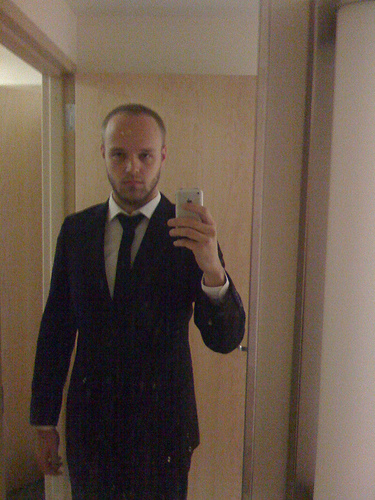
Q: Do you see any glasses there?
A: No, there are no glasses.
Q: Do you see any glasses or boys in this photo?
A: No, there are no glasses or boys.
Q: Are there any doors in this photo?
A: Yes, there is a door.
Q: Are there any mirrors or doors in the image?
A: Yes, there is a door.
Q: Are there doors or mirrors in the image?
A: Yes, there is a door.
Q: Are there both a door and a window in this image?
A: No, there is a door but no windows.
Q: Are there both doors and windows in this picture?
A: No, there is a door but no windows.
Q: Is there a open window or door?
A: Yes, there is an open door.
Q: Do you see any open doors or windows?
A: Yes, there is an open door.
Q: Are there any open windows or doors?
A: Yes, there is an open door.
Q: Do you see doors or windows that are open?
A: Yes, the door is open.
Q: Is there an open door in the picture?
A: Yes, there is an open door.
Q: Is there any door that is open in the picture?
A: Yes, there is an open door.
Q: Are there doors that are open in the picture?
A: Yes, there is an open door.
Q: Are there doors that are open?
A: Yes, there is a door that is open.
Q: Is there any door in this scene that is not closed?
A: Yes, there is a open door.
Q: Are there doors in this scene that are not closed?
A: Yes, there is a open door.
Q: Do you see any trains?
A: No, there are no trains.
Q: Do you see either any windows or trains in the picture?
A: No, there are no trains or windows.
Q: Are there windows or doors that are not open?
A: No, there is a door but it is open.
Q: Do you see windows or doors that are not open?
A: No, there is a door but it is open.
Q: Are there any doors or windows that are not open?
A: No, there is a door but it is open.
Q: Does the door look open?
A: Yes, the door is open.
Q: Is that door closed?
A: No, the door is open.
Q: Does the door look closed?
A: No, the door is open.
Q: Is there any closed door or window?
A: No, there is a door but it is open.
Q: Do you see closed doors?
A: No, there is a door but it is open.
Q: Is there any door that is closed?
A: No, there is a door but it is open.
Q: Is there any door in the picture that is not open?
A: No, there is a door but it is open.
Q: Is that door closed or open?
A: The door is open.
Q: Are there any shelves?
A: No, there are no shelves.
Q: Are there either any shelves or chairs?
A: No, there are no shelves or chairs.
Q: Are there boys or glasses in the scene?
A: No, there are no boys or glasses.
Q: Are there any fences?
A: No, there are no fences.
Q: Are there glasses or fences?
A: No, there are no fences or glasses.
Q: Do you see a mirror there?
A: Yes, there is a mirror.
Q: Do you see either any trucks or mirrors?
A: Yes, there is a mirror.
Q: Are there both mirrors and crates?
A: No, there is a mirror but no crates.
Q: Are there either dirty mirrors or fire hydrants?
A: Yes, there is a dirty mirror.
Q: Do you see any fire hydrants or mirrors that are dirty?
A: Yes, the mirror is dirty.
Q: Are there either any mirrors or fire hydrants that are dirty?
A: Yes, the mirror is dirty.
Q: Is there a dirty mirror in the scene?
A: Yes, there is a dirty mirror.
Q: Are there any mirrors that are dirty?
A: Yes, there is a mirror that is dirty.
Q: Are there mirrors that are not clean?
A: Yes, there is a dirty mirror.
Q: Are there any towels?
A: No, there are no towels.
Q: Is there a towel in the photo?
A: No, there are no towels.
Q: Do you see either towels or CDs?
A: No, there are no towels or cds.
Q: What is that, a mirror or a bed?
A: That is a mirror.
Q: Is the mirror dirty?
A: Yes, the mirror is dirty.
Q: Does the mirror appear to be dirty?
A: Yes, the mirror is dirty.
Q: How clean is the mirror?
A: The mirror is dirty.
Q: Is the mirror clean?
A: No, the mirror is dirty.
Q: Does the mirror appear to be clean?
A: No, the mirror is dirty.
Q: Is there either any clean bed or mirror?
A: No, there is a mirror but it is dirty.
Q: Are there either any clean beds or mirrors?
A: No, there is a mirror but it is dirty.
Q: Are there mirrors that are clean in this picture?
A: No, there is a mirror but it is dirty.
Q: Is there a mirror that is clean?
A: No, there is a mirror but it is dirty.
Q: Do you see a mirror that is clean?
A: No, there is a mirror but it is dirty.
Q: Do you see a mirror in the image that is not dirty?
A: No, there is a mirror but it is dirty.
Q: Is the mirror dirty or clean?
A: The mirror is dirty.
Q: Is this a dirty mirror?
A: Yes, this is a dirty mirror.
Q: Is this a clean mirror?
A: No, this is a dirty mirror.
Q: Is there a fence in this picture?
A: No, there are no fences.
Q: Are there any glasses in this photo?
A: No, there are no glasses.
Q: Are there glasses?
A: No, there are no glasses.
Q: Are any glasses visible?
A: No, there are no glasses.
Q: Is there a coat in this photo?
A: Yes, there is a coat.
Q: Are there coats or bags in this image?
A: Yes, there is a coat.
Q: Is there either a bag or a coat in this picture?
A: Yes, there is a coat.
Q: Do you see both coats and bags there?
A: No, there is a coat but no bags.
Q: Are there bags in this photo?
A: No, there are no bags.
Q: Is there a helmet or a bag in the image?
A: No, there are no bags or helmets.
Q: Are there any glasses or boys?
A: No, there are no glasses or boys.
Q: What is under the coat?
A: The shirt is under the coat.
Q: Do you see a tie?
A: Yes, there is a tie.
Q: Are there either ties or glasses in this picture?
A: Yes, there is a tie.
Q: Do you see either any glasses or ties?
A: Yes, there is a tie.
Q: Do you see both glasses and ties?
A: No, there is a tie but no glasses.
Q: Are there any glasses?
A: No, there are no glasses.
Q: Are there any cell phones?
A: Yes, there is a cell phone.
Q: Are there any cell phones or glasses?
A: Yes, there is a cell phone.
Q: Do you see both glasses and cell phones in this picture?
A: No, there is a cell phone but no glasses.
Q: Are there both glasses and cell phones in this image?
A: No, there is a cell phone but no glasses.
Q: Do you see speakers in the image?
A: No, there are no speakers.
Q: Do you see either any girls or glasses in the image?
A: No, there are no glasses or girls.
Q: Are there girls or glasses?
A: No, there are no glasses or girls.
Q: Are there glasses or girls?
A: No, there are no glasses or girls.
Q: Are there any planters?
A: No, there are no planters.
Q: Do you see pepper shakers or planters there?
A: No, there are no planters or pepper shakers.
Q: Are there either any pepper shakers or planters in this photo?
A: No, there are no planters or pepper shakers.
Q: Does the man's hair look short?
A: Yes, the hair is short.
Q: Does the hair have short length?
A: Yes, the hair is short.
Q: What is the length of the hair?
A: The hair is short.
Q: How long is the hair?
A: The hair is short.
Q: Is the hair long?
A: No, the hair is short.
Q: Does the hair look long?
A: No, the hair is short.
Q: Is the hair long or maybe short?
A: The hair is short.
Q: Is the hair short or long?
A: The hair is short.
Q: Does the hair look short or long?
A: The hair is short.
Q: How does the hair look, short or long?
A: The hair is short.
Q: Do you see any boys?
A: No, there are no boys.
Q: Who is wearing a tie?
A: The man is wearing a tie.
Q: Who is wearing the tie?
A: The man is wearing a tie.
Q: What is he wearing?
A: The man is wearing a tie.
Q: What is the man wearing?
A: The man is wearing a tie.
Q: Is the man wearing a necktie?
A: Yes, the man is wearing a necktie.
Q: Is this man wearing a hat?
A: No, the man is wearing a necktie.